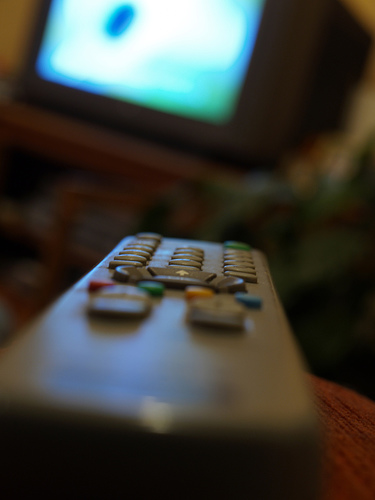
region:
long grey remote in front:
[25, 221, 278, 498]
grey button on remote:
[172, 298, 237, 334]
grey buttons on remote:
[68, 271, 162, 332]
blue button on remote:
[234, 294, 259, 307]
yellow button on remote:
[181, 279, 215, 301]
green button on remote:
[134, 274, 170, 299]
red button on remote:
[89, 274, 113, 293]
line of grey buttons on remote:
[116, 232, 152, 275]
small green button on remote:
[232, 239, 242, 247]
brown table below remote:
[298, 355, 368, 495]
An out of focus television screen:
[18, 2, 368, 169]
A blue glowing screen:
[31, 3, 264, 127]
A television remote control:
[4, 229, 330, 496]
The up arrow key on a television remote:
[148, 263, 217, 286]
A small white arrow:
[173, 267, 191, 278]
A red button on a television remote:
[86, 274, 118, 291]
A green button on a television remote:
[137, 279, 166, 298]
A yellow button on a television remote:
[183, 284, 216, 301]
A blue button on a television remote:
[233, 289, 265, 312]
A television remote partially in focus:
[4, 230, 320, 436]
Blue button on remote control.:
[235, 288, 265, 322]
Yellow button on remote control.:
[184, 282, 215, 299]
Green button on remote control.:
[140, 276, 176, 297]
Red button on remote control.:
[93, 270, 126, 298]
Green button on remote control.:
[222, 239, 255, 249]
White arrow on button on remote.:
[174, 265, 193, 282]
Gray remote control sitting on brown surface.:
[56, 294, 275, 403]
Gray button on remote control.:
[228, 266, 254, 285]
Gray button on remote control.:
[112, 260, 138, 267]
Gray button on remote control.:
[175, 256, 199, 266]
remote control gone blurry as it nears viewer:
[0, 221, 321, 461]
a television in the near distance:
[3, 0, 320, 161]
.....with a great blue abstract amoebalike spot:
[95, 3, 138, 48]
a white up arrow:
[147, 260, 215, 285]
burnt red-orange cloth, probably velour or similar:
[298, 364, 374, 497]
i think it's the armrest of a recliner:
[290, 361, 374, 498]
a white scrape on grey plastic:
[126, 386, 185, 443]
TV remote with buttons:
[8, 221, 318, 443]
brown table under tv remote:
[333, 399, 363, 456]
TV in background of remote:
[18, 0, 280, 164]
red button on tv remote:
[85, 272, 116, 295]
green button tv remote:
[137, 276, 172, 295]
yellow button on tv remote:
[176, 283, 214, 301]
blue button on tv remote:
[232, 289, 270, 312]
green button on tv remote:
[218, 235, 257, 252]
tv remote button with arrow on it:
[145, 260, 217, 281]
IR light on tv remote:
[117, 390, 180, 439]